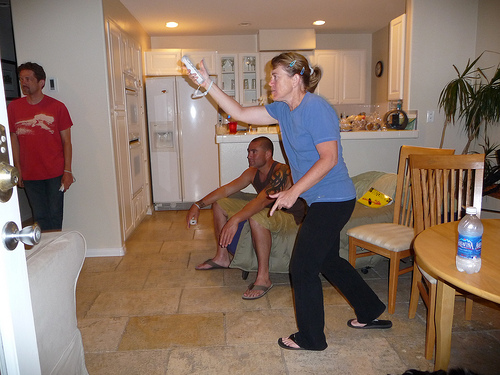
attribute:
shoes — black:
[278, 304, 405, 359]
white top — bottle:
[463, 205, 475, 220]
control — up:
[175, 52, 210, 85]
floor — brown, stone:
[81, 209, 498, 371]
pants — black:
[259, 179, 420, 346]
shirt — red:
[4, 96, 73, 180]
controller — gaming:
[179, 50, 215, 99]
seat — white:
[351, 216, 419, 243]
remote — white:
[183, 51, 203, 81]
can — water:
[455, 202, 482, 274]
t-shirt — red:
[5, 101, 66, 180]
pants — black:
[276, 189, 390, 352]